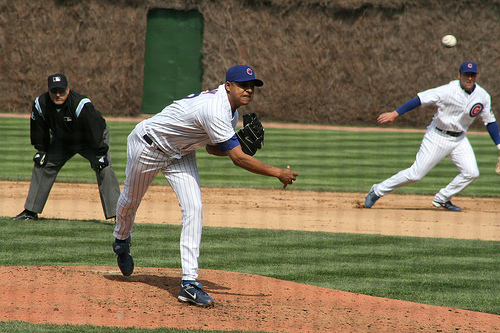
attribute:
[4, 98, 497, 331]
lawn — green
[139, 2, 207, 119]
door — green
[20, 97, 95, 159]
jacket — black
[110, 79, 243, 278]
uniform — white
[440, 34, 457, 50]
ball — white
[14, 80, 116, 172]
jacket — dark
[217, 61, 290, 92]
cap — blue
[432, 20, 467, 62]
ball — white, small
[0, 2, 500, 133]
wall — brown 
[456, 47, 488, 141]
cap — blue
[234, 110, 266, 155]
glove — black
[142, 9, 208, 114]
door — green 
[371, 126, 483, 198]
pants — white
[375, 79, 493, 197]
team uniform — white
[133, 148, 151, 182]
stripes — thin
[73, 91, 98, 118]
stripes — light blue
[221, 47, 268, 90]
hat — blue 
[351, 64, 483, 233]
player — baseball